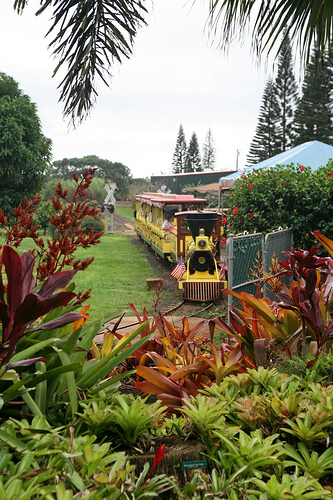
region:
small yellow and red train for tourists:
[132, 192, 227, 312]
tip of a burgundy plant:
[0, 167, 104, 366]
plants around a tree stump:
[2, 302, 332, 499]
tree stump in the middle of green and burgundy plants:
[100, 435, 207, 498]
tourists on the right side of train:
[133, 191, 176, 259]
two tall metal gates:
[225, 226, 294, 329]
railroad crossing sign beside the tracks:
[100, 182, 116, 234]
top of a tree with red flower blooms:
[220, 157, 332, 223]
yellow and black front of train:
[176, 208, 224, 302]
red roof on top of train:
[136, 190, 206, 204]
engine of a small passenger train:
[172, 212, 231, 289]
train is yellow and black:
[175, 205, 228, 294]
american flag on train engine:
[160, 244, 194, 285]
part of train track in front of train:
[141, 287, 186, 334]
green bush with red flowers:
[234, 172, 309, 234]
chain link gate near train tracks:
[226, 216, 311, 321]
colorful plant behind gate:
[277, 243, 329, 335]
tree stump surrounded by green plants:
[119, 427, 214, 474]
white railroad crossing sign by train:
[102, 173, 126, 200]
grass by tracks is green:
[107, 257, 143, 298]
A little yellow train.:
[113, 176, 230, 304]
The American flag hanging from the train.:
[165, 250, 185, 282]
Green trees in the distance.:
[143, 111, 219, 165]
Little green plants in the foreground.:
[0, 395, 331, 494]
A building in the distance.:
[136, 157, 238, 190]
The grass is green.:
[95, 245, 137, 303]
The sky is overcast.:
[134, 54, 240, 100]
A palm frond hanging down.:
[194, 0, 329, 69]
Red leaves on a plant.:
[3, 242, 82, 335]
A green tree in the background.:
[2, 72, 48, 217]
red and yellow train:
[138, 187, 231, 307]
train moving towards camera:
[132, 186, 231, 303]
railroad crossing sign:
[103, 178, 120, 234]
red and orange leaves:
[1, 166, 332, 399]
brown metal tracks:
[106, 201, 231, 347]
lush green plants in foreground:
[1, 320, 330, 499]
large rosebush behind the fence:
[213, 157, 331, 294]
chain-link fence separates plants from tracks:
[229, 226, 298, 334]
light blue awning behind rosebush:
[219, 134, 332, 211]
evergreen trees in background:
[170, 28, 332, 175]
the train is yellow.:
[127, 186, 230, 319]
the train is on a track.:
[124, 175, 232, 335]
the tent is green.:
[209, 127, 331, 199]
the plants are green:
[2, 338, 332, 497]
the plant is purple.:
[2, 236, 84, 361]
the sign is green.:
[178, 455, 210, 473]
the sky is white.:
[0, 1, 331, 181]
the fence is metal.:
[220, 218, 298, 335]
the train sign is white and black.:
[96, 179, 120, 236]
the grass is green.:
[6, 229, 161, 335]